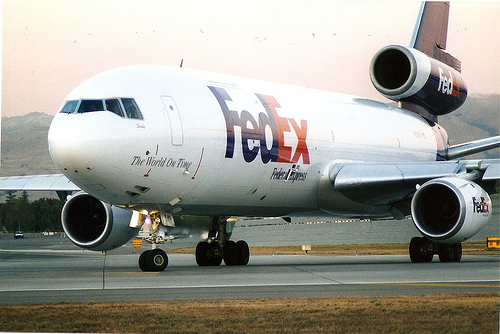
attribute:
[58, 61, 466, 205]
plane — white, landing, long, large, parked, orange, fedex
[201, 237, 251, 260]
wheels — black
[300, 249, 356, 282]
runway — long, grey, gray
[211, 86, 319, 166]
letters — orange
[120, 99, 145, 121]
window — small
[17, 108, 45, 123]
mountains — far